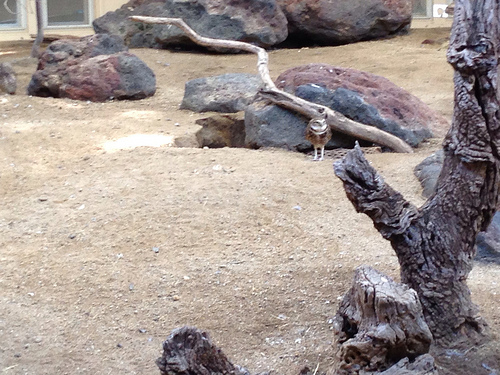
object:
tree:
[336, 0, 498, 346]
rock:
[24, 31, 159, 105]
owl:
[294, 113, 338, 164]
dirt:
[64, 110, 155, 225]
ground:
[158, 181, 342, 270]